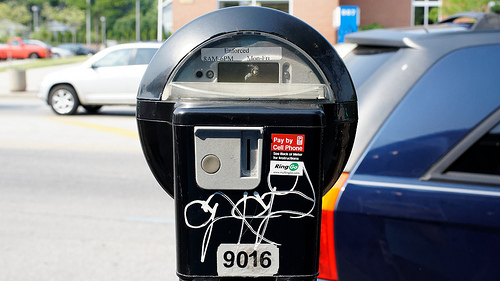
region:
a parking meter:
[140, 5, 349, 280]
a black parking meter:
[134, 3, 361, 279]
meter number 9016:
[137, 6, 359, 279]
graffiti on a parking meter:
[135, 4, 360, 279]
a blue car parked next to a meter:
[134, 19, 496, 279]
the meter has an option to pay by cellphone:
[267, 131, 310, 180]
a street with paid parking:
[22, 1, 499, 278]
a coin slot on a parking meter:
[194, 125, 270, 190]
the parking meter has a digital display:
[215, 60, 288, 90]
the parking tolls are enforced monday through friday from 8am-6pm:
[198, 44, 290, 63]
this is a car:
[26, 45, 138, 113]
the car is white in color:
[91, 70, 118, 94]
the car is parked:
[21, 43, 138, 111]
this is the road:
[15, 120, 137, 277]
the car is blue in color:
[421, 84, 449, 136]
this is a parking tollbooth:
[176, 105, 315, 278]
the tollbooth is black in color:
[143, 110, 170, 140]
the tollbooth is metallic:
[143, 100, 191, 145]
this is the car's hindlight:
[319, 204, 331, 266]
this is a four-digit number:
[216, 244, 284, 279]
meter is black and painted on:
[134, 0, 386, 280]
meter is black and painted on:
[121, 2, 398, 279]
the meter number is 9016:
[214, 240, 284, 278]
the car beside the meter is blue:
[260, 11, 497, 279]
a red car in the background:
[3, 28, 60, 67]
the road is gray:
[6, 112, 166, 274]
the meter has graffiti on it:
[183, 164, 319, 264]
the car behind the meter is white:
[38, 35, 224, 135]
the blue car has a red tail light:
[310, 168, 499, 279]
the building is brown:
[159, 2, 499, 67]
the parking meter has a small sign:
[260, 123, 319, 185]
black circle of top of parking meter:
[88, 8, 389, 208]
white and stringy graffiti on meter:
[165, 167, 316, 262]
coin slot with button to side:
[185, 120, 265, 185]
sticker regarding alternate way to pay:
[260, 120, 305, 175]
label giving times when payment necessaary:
[195, 45, 290, 60]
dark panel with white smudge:
[212, 60, 279, 80]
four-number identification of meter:
[200, 235, 292, 275]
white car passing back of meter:
[25, 22, 195, 122]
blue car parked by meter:
[306, 10, 486, 275]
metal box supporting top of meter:
[150, 70, 355, 277]